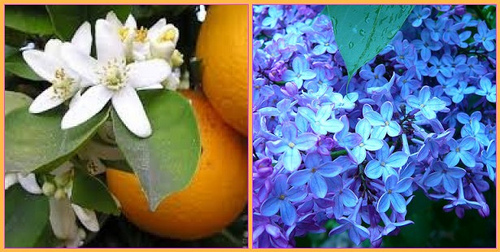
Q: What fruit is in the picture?
A: Oranges.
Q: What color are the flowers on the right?
A: Blue.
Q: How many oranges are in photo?
A: Two.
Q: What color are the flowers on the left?
A: White.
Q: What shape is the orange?
A: Round.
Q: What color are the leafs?
A: Green.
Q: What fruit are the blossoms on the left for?
A: Orange.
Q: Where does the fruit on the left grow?
A: Tree.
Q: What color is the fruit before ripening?
A: Green.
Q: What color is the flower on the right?
A: Blue.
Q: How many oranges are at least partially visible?
A: 2.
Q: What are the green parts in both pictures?
A: Leaves.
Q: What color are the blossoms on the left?
A: White.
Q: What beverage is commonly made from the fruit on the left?
A: Orange juice.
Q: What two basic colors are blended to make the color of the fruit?
A: Red and yellow.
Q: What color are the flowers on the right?
A: Purple.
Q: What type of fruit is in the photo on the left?
A: Oranges.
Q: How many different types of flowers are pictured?
A: 2.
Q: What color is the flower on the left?
A: White.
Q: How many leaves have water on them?
A: 1.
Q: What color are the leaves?
A: Green.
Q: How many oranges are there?
A: 2.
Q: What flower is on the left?
A: Orange blossom.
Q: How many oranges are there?
A: Two.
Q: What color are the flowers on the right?
A: Violet.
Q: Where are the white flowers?
A: Near the oranges.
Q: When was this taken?
A: During the day.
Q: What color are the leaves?
A: Green.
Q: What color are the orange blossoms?
A: White and yellow.